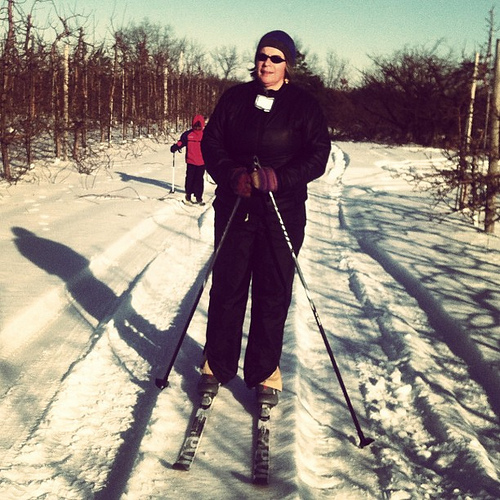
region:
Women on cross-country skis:
[155, 28, 373, 486]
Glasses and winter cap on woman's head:
[251, 28, 296, 87]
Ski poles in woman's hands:
[153, 166, 373, 449]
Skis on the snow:
[170, 378, 276, 484]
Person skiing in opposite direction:
[170, 116, 206, 207]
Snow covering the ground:
[5, 136, 498, 497]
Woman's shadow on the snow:
[9, 219, 172, 367]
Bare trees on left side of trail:
[2, 2, 233, 181]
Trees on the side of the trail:
[436, 42, 498, 230]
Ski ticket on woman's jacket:
[255, 93, 274, 114]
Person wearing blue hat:
[244, 23, 305, 93]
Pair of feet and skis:
[172, 369, 282, 491]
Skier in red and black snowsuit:
[165, 105, 216, 210]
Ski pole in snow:
[265, 190, 383, 452]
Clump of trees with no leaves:
[375, 50, 466, 142]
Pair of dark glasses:
[252, 49, 288, 64]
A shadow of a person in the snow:
[8, 220, 181, 379]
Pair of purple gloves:
[229, 154, 279, 206]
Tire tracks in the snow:
[345, 215, 480, 370]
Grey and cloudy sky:
[332, 25, 436, 56]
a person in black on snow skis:
[168, 20, 375, 482]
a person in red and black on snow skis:
[167, 107, 221, 207]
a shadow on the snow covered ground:
[11, 213, 193, 373]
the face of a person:
[255, 48, 285, 85]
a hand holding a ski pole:
[167, 141, 179, 203]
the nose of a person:
[263, 58, 274, 69]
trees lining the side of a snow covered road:
[11, 29, 180, 183]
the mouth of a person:
[256, 68, 280, 80]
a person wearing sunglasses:
[251, 31, 300, 85]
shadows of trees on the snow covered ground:
[329, 184, 499, 499]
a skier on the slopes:
[94, 34, 386, 344]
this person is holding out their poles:
[131, 162, 363, 424]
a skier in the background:
[166, 105, 218, 220]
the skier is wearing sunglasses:
[228, 37, 323, 110]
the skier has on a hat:
[253, 27, 295, 95]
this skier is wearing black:
[213, 87, 300, 392]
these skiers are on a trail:
[147, 44, 350, 426]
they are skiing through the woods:
[104, 35, 391, 405]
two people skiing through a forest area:
[87, 45, 395, 340]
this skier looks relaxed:
[214, 15, 324, 170]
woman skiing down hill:
[89, 11, 391, 485]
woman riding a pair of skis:
[103, 22, 411, 482]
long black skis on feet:
[152, 399, 217, 476]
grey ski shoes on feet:
[188, 373, 277, 399]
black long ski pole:
[117, 200, 242, 391]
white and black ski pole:
[275, 205, 388, 453]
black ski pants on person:
[180, 199, 315, 379]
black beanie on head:
[249, 25, 294, 60]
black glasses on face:
[250, 46, 284, 68]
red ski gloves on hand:
[227, 169, 282, 196]